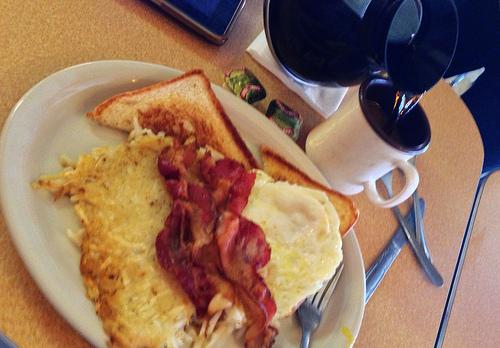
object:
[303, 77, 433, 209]
coffee mug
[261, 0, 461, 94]
coffee pot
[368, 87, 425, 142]
coffee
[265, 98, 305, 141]
pack of butter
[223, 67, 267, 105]
pack of butter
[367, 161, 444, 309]
silverware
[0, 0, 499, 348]
table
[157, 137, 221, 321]
bacon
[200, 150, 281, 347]
bacon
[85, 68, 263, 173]
toast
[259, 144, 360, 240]
toast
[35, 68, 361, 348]
breakfast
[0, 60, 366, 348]
plate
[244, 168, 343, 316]
egg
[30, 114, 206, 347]
hash browns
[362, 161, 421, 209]
handle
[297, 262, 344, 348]
fork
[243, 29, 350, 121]
napkin